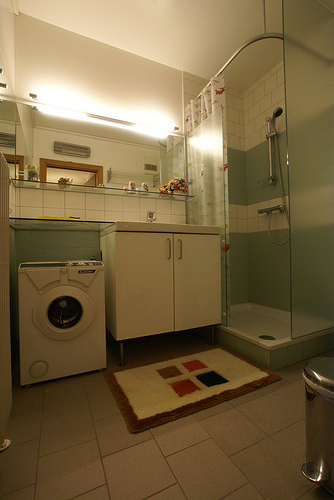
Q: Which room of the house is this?
A: It is a bathroom.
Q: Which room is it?
A: It is a bathroom.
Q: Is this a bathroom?
A: Yes, it is a bathroom.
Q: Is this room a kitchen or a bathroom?
A: It is a bathroom.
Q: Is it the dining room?
A: No, it is the bathroom.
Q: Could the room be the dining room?
A: No, it is the bathroom.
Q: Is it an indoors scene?
A: Yes, it is indoors.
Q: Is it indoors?
A: Yes, it is indoors.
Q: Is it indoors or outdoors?
A: It is indoors.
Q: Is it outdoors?
A: No, it is indoors.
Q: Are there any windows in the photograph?
A: Yes, there is a window.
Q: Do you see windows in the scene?
A: Yes, there is a window.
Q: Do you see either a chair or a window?
A: Yes, there is a window.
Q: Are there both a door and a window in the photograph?
A: Yes, there are both a window and a door.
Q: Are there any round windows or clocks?
A: Yes, there is a round window.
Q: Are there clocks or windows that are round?
A: Yes, the window is round.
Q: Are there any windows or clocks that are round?
A: Yes, the window is round.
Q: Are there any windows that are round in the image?
A: Yes, there is a round window.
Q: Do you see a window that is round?
A: Yes, there is a window that is round.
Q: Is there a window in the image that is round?
A: Yes, there is a window that is round.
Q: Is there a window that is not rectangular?
A: Yes, there is a round window.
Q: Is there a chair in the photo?
A: No, there are no chairs.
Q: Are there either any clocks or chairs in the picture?
A: No, there are no chairs or clocks.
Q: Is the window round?
A: Yes, the window is round.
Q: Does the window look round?
A: Yes, the window is round.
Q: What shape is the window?
A: The window is round.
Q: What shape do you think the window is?
A: The window is round.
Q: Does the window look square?
A: No, the window is round.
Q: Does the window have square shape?
A: No, the window is round.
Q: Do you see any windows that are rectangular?
A: No, there is a window but it is round.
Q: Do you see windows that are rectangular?
A: No, there is a window but it is round.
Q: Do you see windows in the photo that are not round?
A: No, there is a window but it is round.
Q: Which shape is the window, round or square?
A: The window is round.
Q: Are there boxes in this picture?
A: No, there are no boxes.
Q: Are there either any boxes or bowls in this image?
A: No, there are no boxes or bowls.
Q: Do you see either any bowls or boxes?
A: No, there are no boxes or bowls.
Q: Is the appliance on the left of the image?
A: Yes, the appliance is on the left of the image.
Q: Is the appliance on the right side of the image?
A: No, the appliance is on the left of the image.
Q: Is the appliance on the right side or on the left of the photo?
A: The appliance is on the left of the image.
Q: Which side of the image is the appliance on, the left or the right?
A: The appliance is on the left of the image.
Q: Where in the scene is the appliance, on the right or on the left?
A: The appliance is on the left of the image.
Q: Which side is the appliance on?
A: The appliance is on the left of the image.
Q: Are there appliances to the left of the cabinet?
A: Yes, there is an appliance to the left of the cabinet.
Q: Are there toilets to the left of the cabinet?
A: No, there is an appliance to the left of the cabinet.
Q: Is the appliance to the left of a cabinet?
A: Yes, the appliance is to the left of a cabinet.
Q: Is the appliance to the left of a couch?
A: No, the appliance is to the left of a cabinet.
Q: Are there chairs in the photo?
A: No, there are no chairs.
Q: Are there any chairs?
A: No, there are no chairs.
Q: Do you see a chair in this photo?
A: No, there are no chairs.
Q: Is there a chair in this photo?
A: No, there are no chairs.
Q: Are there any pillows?
A: No, there are no pillows.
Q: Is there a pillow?
A: No, there are no pillows.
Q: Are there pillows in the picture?
A: No, there are no pillows.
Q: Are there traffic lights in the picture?
A: No, there are no traffic lights.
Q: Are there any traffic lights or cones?
A: No, there are no traffic lights or cones.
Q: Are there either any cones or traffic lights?
A: No, there are no traffic lights or cones.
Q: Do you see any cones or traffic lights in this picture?
A: No, there are no traffic lights or cones.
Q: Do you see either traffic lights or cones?
A: No, there are no traffic lights or cones.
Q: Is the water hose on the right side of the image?
A: Yes, the water hose is on the right of the image.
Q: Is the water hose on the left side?
A: No, the water hose is on the right of the image.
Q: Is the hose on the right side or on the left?
A: The hose is on the right of the image.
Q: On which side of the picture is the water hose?
A: The water hose is on the right of the image.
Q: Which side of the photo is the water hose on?
A: The water hose is on the right of the image.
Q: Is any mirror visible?
A: Yes, there is a mirror.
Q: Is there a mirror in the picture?
A: Yes, there is a mirror.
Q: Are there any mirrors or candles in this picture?
A: Yes, there is a mirror.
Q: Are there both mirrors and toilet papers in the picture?
A: No, there is a mirror but no toilet papers.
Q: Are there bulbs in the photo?
A: No, there are no bulbs.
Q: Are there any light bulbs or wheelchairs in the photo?
A: No, there are no light bulbs or wheelchairs.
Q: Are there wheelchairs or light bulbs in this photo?
A: No, there are no light bulbs or wheelchairs.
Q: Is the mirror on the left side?
A: Yes, the mirror is on the left of the image.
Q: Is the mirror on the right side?
A: No, the mirror is on the left of the image.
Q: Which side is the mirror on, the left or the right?
A: The mirror is on the left of the image.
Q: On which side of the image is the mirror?
A: The mirror is on the left of the image.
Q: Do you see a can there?
A: Yes, there is a can.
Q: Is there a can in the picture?
A: Yes, there is a can.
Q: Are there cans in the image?
A: Yes, there is a can.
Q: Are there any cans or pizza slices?
A: Yes, there is a can.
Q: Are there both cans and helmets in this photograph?
A: No, there is a can but no helmets.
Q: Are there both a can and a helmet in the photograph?
A: No, there is a can but no helmets.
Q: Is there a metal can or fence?
A: Yes, there is a metal can.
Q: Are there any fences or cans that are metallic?
A: Yes, the can is metallic.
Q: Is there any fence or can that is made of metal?
A: Yes, the can is made of metal.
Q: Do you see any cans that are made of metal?
A: Yes, there is a can that is made of metal.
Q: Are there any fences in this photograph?
A: No, there are no fences.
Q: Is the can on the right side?
A: Yes, the can is on the right of the image.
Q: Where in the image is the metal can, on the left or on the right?
A: The can is on the right of the image.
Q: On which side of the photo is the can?
A: The can is on the right of the image.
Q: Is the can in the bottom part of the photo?
A: Yes, the can is in the bottom of the image.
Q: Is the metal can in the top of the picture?
A: No, the can is in the bottom of the image.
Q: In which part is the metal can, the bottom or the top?
A: The can is in the bottom of the image.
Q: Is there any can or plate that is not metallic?
A: No, there is a can but it is metallic.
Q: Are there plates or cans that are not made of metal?
A: No, there is a can but it is made of metal.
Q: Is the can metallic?
A: Yes, the can is metallic.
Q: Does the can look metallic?
A: Yes, the can is metallic.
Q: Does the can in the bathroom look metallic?
A: Yes, the can is metallic.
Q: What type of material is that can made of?
A: The can is made of metal.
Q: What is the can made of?
A: The can is made of metal.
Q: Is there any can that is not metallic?
A: No, there is a can but it is metallic.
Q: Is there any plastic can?
A: No, there is a can but it is made of metal.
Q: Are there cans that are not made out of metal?
A: No, there is a can but it is made of metal.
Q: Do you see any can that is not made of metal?
A: No, there is a can but it is made of metal.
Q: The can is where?
A: The can is in the bathroom.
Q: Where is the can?
A: The can is in the bathroom.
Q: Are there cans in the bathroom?
A: Yes, there is a can in the bathroom.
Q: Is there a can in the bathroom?
A: Yes, there is a can in the bathroom.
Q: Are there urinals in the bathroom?
A: No, there is a can in the bathroom.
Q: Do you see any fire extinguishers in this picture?
A: No, there are no fire extinguishers.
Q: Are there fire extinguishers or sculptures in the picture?
A: No, there are no fire extinguishers or sculptures.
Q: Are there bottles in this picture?
A: No, there are no bottles.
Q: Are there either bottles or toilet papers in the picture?
A: No, there are no bottles or toilet papers.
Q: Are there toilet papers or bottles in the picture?
A: No, there are no bottles or toilet papers.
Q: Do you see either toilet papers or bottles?
A: No, there are no bottles or toilet papers.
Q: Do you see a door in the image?
A: Yes, there are doors.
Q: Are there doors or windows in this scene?
A: Yes, there are doors.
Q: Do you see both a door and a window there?
A: Yes, there are both a door and a window.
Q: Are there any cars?
A: No, there are no cars.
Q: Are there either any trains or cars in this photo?
A: No, there are no cars or trains.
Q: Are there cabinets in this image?
A: Yes, there is a cabinet.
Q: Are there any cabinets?
A: Yes, there is a cabinet.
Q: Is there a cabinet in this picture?
A: Yes, there is a cabinet.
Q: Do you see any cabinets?
A: Yes, there is a cabinet.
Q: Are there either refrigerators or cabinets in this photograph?
A: Yes, there is a cabinet.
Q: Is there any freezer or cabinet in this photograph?
A: Yes, there is a cabinet.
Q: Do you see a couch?
A: No, there are no couches.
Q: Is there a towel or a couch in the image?
A: No, there are no couches or towels.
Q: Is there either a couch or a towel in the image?
A: No, there are no couches or towels.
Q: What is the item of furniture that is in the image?
A: The piece of furniture is a cabinet.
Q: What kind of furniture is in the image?
A: The furniture is a cabinet.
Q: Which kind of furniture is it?
A: The piece of furniture is a cabinet.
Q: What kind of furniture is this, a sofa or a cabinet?
A: That is a cabinet.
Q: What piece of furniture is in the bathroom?
A: The piece of furniture is a cabinet.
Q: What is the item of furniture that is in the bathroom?
A: The piece of furniture is a cabinet.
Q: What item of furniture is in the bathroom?
A: The piece of furniture is a cabinet.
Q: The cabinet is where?
A: The cabinet is in the bathroom.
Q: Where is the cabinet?
A: The cabinet is in the bathroom.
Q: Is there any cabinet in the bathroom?
A: Yes, there is a cabinet in the bathroom.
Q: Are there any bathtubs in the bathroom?
A: No, there is a cabinet in the bathroom.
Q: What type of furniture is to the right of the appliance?
A: The piece of furniture is a cabinet.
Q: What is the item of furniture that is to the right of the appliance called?
A: The piece of furniture is a cabinet.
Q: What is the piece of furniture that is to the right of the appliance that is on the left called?
A: The piece of furniture is a cabinet.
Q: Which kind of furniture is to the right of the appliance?
A: The piece of furniture is a cabinet.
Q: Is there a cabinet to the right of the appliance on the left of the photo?
A: Yes, there is a cabinet to the right of the appliance.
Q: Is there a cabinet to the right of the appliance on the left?
A: Yes, there is a cabinet to the right of the appliance.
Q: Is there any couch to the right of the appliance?
A: No, there is a cabinet to the right of the appliance.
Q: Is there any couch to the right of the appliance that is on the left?
A: No, there is a cabinet to the right of the appliance.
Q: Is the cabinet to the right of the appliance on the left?
A: Yes, the cabinet is to the right of the appliance.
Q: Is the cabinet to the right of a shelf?
A: No, the cabinet is to the right of the appliance.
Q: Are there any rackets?
A: No, there are no rackets.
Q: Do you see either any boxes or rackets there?
A: No, there are no rackets or boxes.